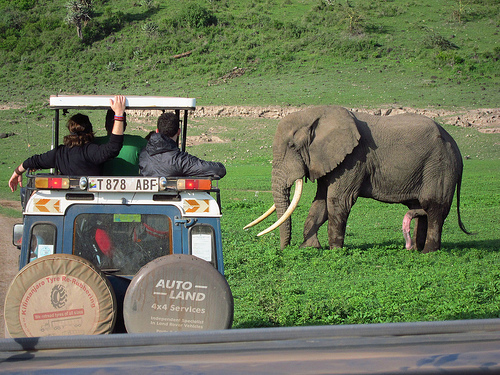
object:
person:
[94, 108, 148, 176]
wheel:
[123, 253, 234, 334]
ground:
[393, 172, 408, 198]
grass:
[0, 0, 500, 328]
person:
[138, 113, 226, 177]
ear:
[308, 106, 361, 183]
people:
[8, 95, 126, 192]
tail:
[457, 177, 474, 234]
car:
[2, 94, 235, 339]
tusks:
[242, 204, 276, 230]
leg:
[417, 197, 453, 254]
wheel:
[4, 253, 117, 339]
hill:
[0, 2, 500, 109]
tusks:
[256, 179, 303, 237]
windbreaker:
[137, 133, 226, 178]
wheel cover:
[122, 253, 234, 334]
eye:
[288, 141, 297, 150]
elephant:
[242, 105, 479, 255]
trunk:
[271, 154, 292, 250]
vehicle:
[2, 94, 233, 339]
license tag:
[87, 176, 160, 193]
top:
[49, 94, 195, 110]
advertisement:
[150, 279, 208, 333]